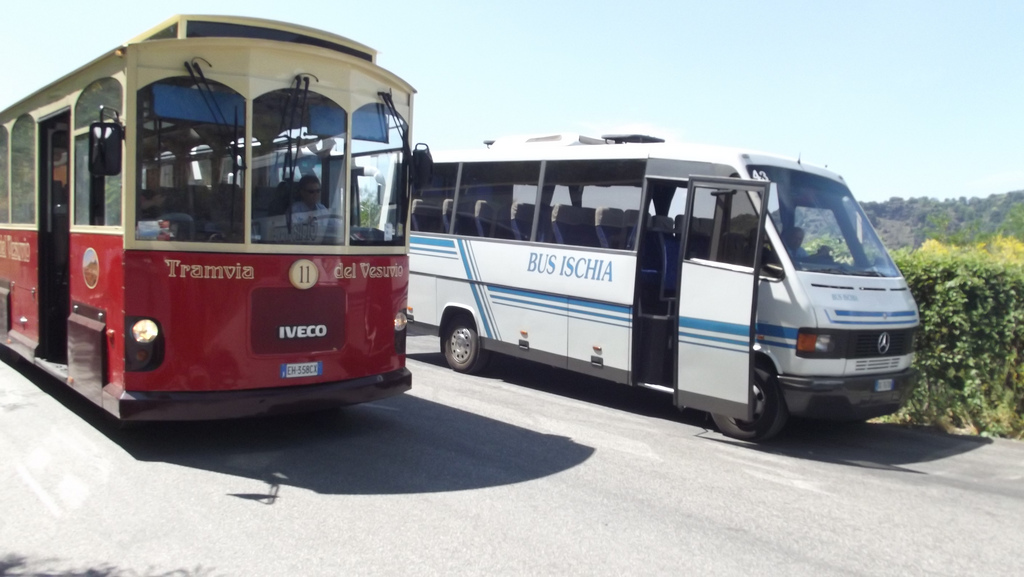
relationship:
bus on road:
[2, 14, 436, 423] [2, 323, 1023, 574]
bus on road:
[455, 114, 788, 410] [535, 403, 814, 538]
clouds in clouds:
[3, 3, 1019, 204] [0, 0, 1024, 204]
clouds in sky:
[3, 3, 1019, 204] [600, 48, 856, 135]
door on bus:
[673, 172, 771, 422] [408, 132, 923, 442]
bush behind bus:
[799, 237, 1022, 438] [408, 132, 923, 442]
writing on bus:
[164, 257, 256, 281] [0, 14, 416, 423]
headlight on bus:
[114, 310, 160, 347] [0, 14, 416, 423]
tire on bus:
[441, 320, 484, 371] [408, 132, 923, 442]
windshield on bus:
[138, 79, 408, 244] [0, 14, 416, 423]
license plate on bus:
[284, 360, 320, 381] [0, 14, 416, 423]